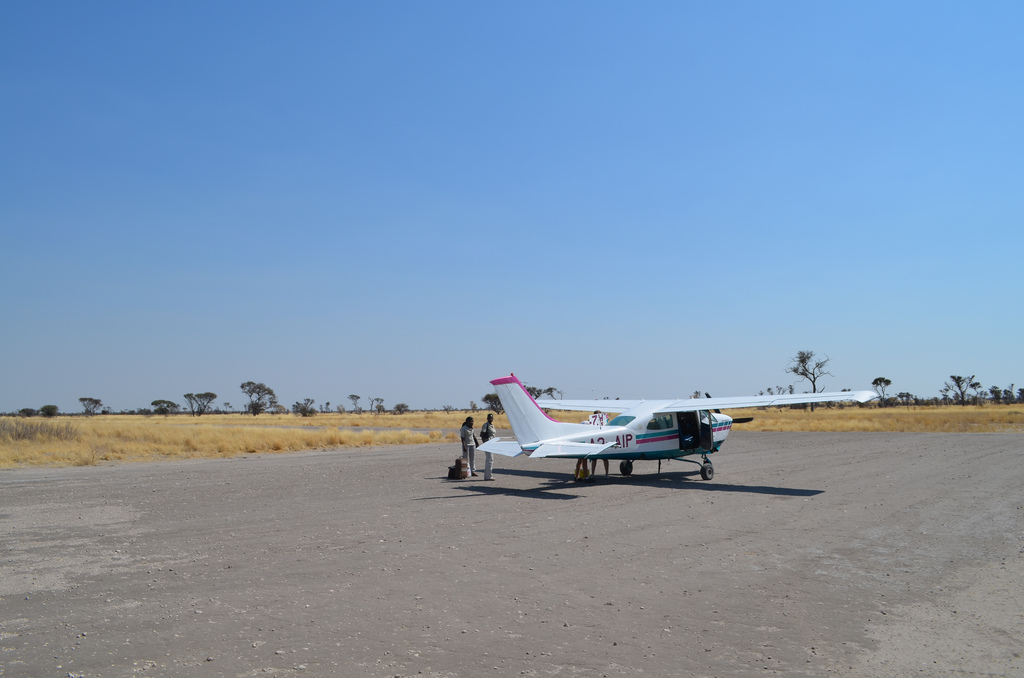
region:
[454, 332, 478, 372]
An Asian woman is holding a purse.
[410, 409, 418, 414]
An Asian woman is holding a purse.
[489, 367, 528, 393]
Tip of tail is red on plane.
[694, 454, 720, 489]
Black wheel on plane.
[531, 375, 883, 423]
White wings on plane.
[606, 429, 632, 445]
Black letters on side of plane.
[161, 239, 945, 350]
Sky is blue and clear.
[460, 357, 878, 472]
Airplane sitting on pavement.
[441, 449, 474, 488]
Bags sitting on pavement.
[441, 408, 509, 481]
2 people standing near plane.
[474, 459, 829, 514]
Shadow of plane on pavement.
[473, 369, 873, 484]
plane on the runway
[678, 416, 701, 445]
door of the plane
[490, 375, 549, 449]
tail of the plane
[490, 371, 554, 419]
red paint on tail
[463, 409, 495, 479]
two people near plane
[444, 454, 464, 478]
luggage on the ground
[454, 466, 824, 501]
shadow on the ground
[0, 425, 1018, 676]
the tarmac is gray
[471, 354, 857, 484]
a plane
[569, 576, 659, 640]
the ground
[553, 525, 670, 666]
the ground is grey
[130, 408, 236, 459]
the grass is brown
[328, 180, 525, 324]
a clear blue sky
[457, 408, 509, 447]
two people standing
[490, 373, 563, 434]
tail of the airplane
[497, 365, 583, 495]
fin on a plane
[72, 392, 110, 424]
tree in a field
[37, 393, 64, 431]
tree in a field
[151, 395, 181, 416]
tree in a field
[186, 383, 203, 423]
tree in a field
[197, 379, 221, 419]
tree in a field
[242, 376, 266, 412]
tree in a field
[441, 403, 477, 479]
person standing on runway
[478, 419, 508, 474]
person standing on runway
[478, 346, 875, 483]
small white and red plane on runway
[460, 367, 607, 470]
tail of the plane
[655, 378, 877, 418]
right wing of the plane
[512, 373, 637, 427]
left wing of the plane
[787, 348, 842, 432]
large tree in the background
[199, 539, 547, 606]
gray color on the ground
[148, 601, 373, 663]
small pebbles on the ground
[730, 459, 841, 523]
plane's shadow cast on the ground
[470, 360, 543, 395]
pink color on end of plane's wing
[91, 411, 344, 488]
yellow grass on the ground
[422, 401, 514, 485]
people standing beside small plane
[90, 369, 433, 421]
large area of green trees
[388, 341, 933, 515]
small plane on the runway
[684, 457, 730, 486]
black wheel on the plane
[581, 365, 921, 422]
white wing on the plane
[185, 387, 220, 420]
A tree in a field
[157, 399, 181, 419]
A tree in a field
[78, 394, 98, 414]
A tree in a field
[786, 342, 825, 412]
A tree in a field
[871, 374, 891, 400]
A tree in a field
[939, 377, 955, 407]
A tree in a field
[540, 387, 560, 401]
A tree in a field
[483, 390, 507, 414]
A tree in a field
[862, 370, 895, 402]
A tree in the distance.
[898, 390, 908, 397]
A tree in the distance.